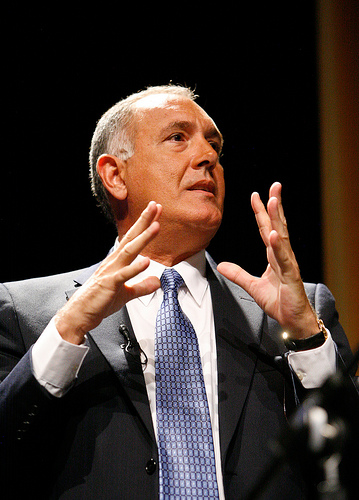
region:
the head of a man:
[47, 50, 266, 308]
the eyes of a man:
[152, 118, 239, 151]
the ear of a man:
[80, 101, 165, 239]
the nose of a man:
[182, 127, 231, 185]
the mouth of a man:
[179, 164, 240, 207]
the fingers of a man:
[96, 194, 176, 306]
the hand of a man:
[50, 191, 181, 403]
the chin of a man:
[142, 196, 245, 302]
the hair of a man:
[73, 28, 237, 230]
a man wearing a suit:
[80, 18, 330, 421]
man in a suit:
[11, 60, 337, 478]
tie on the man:
[134, 260, 231, 498]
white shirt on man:
[129, 240, 244, 497]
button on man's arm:
[16, 391, 37, 443]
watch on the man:
[277, 316, 328, 348]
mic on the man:
[106, 317, 138, 357]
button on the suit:
[137, 451, 155, 475]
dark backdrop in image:
[15, 5, 318, 258]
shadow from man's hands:
[208, 313, 272, 404]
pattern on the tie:
[170, 421, 188, 450]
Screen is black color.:
[16, 35, 317, 243]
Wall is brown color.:
[321, 66, 357, 288]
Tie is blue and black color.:
[149, 294, 211, 440]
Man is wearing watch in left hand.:
[267, 315, 338, 365]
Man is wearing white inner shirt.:
[112, 241, 227, 421]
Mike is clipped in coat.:
[115, 316, 148, 373]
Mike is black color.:
[112, 313, 154, 374]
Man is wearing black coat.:
[2, 269, 349, 493]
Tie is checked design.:
[157, 329, 217, 498]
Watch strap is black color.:
[277, 325, 327, 355]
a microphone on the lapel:
[115, 323, 147, 365]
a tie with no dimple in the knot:
[158, 268, 219, 498]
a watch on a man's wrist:
[286, 319, 327, 352]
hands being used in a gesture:
[48, 180, 336, 352]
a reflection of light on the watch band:
[280, 329, 289, 340]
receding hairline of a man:
[117, 86, 226, 129]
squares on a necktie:
[189, 420, 202, 435]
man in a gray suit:
[0, 85, 356, 498]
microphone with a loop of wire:
[117, 318, 149, 366]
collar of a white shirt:
[114, 242, 212, 306]